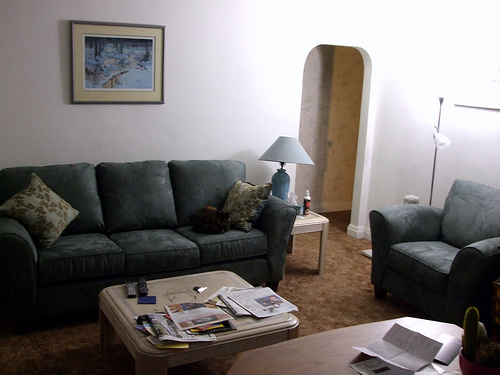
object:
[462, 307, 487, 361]
cactus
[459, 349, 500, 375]
pot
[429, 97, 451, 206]
stand lamp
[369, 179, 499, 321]
chair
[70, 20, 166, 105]
picture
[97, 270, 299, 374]
coffee table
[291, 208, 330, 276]
table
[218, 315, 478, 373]
table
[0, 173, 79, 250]
pillow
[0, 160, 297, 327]
couch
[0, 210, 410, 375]
floor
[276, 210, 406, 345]
carpet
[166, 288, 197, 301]
glasses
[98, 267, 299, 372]
table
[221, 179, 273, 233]
pillow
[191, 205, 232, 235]
cat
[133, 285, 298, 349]
newspaper/table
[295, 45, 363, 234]
door way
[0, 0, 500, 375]
living room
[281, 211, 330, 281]
end table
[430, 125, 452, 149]
lamp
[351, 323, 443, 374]
paper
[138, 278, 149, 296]
remote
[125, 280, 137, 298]
remote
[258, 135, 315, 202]
lamp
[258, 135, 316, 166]
shade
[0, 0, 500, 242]
wall